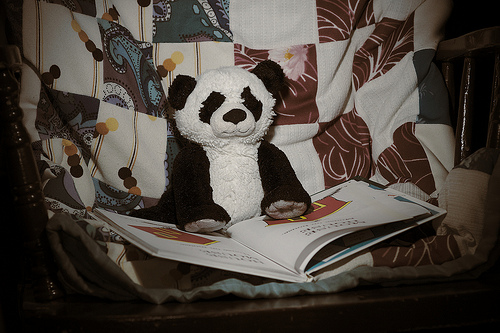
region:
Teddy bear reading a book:
[118, 61, 329, 214]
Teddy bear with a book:
[87, 70, 282, 280]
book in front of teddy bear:
[136, 180, 321, 303]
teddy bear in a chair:
[138, 68, 283, 244]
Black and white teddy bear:
[144, 64, 317, 231]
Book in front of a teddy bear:
[143, 165, 351, 282]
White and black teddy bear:
[136, 30, 308, 172]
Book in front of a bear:
[114, 203, 393, 285]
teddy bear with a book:
[117, 135, 369, 331]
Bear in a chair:
[87, 85, 344, 245]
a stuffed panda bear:
[157, 57, 314, 231]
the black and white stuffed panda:
[157, 54, 310, 231]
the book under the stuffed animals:
[96, 170, 454, 284]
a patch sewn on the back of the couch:
[95, 13, 171, 118]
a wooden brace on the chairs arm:
[456, 52, 474, 163]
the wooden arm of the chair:
[434, 24, 497, 60]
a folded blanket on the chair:
[15, 11, 477, 291]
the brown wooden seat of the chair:
[55, 284, 499, 331]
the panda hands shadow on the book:
[200, 224, 235, 246]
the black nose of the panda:
[222, 104, 247, 129]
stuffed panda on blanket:
[151, 63, 313, 228]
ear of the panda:
[251, 60, 283, 100]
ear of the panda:
[173, 75, 186, 116]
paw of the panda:
[183, 208, 226, 234]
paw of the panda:
[272, 198, 310, 222]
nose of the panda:
[223, 109, 246, 133]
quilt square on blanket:
[100, 28, 164, 114]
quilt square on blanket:
[323, 118, 370, 180]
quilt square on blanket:
[169, 0, 227, 42]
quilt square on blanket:
[44, 97, 96, 151]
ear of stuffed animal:
[247, 53, 294, 101]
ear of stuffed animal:
[164, 68, 198, 117]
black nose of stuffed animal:
[221, 106, 246, 125]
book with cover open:
[76, 156, 437, 283]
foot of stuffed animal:
[257, 183, 318, 225]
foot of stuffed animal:
[179, 203, 234, 238]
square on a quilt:
[227, 38, 324, 132]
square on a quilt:
[310, 27, 367, 127]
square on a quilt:
[312, 98, 384, 195]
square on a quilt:
[85, 100, 177, 200]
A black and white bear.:
[130, 58, 312, 235]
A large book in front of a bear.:
[85, 177, 449, 282]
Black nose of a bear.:
[221, 108, 247, 123]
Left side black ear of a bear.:
[166, 73, 197, 108]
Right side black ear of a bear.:
[252, 59, 284, 99]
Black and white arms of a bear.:
[169, 143, 310, 229]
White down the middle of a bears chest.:
[203, 141, 263, 222]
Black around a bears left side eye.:
[198, 91, 227, 126]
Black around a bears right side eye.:
[240, 85, 263, 122]